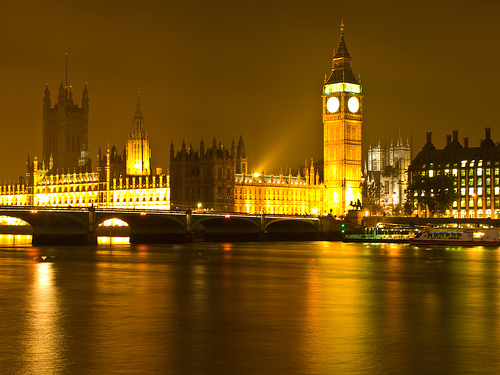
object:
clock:
[325, 96, 340, 113]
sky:
[1, 5, 500, 137]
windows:
[460, 178, 466, 186]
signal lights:
[28, 205, 40, 216]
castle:
[358, 125, 416, 219]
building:
[0, 150, 167, 210]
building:
[234, 155, 325, 220]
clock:
[347, 96, 360, 113]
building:
[172, 134, 247, 217]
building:
[324, 21, 361, 215]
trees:
[403, 169, 459, 221]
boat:
[340, 222, 416, 243]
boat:
[408, 219, 500, 247]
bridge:
[0, 203, 329, 246]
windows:
[428, 169, 434, 177]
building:
[36, 55, 91, 170]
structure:
[320, 20, 367, 185]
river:
[0, 242, 500, 373]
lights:
[469, 186, 477, 198]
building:
[411, 126, 500, 219]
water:
[16, 242, 463, 372]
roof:
[129, 85, 150, 137]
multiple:
[410, 125, 500, 221]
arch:
[93, 214, 187, 247]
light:
[217, 240, 237, 252]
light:
[223, 213, 233, 219]